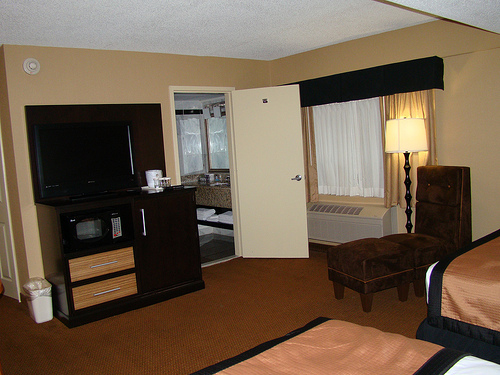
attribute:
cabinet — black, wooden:
[45, 202, 199, 317]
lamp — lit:
[384, 118, 429, 236]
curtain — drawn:
[313, 102, 382, 197]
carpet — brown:
[208, 267, 322, 315]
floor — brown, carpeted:
[11, 329, 184, 373]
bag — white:
[22, 277, 54, 302]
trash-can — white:
[28, 294, 53, 325]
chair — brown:
[416, 166, 471, 255]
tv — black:
[32, 120, 136, 199]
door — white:
[229, 85, 311, 260]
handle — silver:
[291, 173, 304, 184]